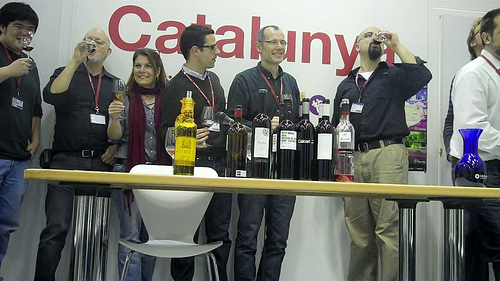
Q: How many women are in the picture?
A: One.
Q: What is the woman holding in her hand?
A: A glass.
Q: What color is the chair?
A: White.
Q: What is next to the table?
A: A chair.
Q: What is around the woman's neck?
A: A scarf.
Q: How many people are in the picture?
A: Eight.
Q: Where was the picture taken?
A: At a wine tasting.